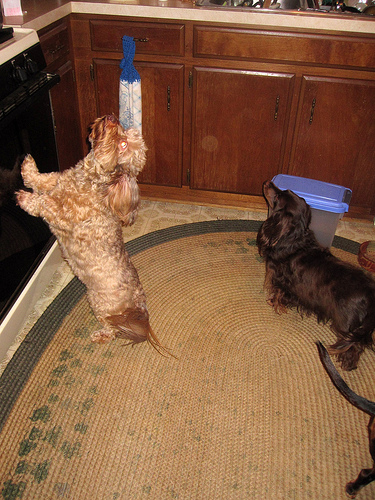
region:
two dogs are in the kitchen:
[15, 110, 369, 359]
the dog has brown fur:
[13, 110, 176, 364]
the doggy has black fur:
[255, 177, 373, 369]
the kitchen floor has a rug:
[6, 186, 374, 474]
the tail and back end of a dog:
[308, 335, 373, 491]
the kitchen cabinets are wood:
[41, 10, 373, 218]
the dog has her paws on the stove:
[0, 17, 131, 367]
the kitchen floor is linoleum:
[52, 196, 374, 263]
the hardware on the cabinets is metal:
[50, 2, 373, 185]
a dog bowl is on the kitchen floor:
[356, 235, 374, 276]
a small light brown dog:
[20, 105, 182, 373]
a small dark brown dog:
[249, 175, 372, 345]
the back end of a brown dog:
[306, 333, 374, 495]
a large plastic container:
[271, 170, 346, 255]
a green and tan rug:
[0, 219, 372, 496]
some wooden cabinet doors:
[85, 22, 373, 213]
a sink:
[194, 1, 374, 18]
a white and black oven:
[0, 39, 90, 367]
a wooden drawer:
[81, 19, 192, 55]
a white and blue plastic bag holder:
[115, 35, 147, 162]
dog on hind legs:
[13, 128, 158, 371]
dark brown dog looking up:
[242, 179, 363, 362]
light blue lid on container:
[271, 167, 358, 259]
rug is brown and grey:
[63, 217, 317, 498]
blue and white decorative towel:
[103, 37, 153, 157]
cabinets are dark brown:
[93, 24, 357, 190]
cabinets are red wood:
[82, 19, 349, 190]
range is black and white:
[0, 34, 65, 296]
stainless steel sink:
[205, 0, 343, 17]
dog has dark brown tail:
[107, 294, 191, 384]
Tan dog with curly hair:
[0, 17, 182, 371]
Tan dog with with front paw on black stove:
[5, 30, 182, 374]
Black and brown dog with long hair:
[230, 154, 373, 364]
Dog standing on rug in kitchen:
[233, 162, 373, 350]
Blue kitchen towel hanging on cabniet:
[101, 26, 168, 140]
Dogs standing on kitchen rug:
[21, 109, 372, 385]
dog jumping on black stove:
[17, 111, 202, 369]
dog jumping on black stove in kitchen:
[15, 98, 192, 361]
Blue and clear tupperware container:
[234, 128, 364, 269]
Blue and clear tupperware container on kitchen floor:
[244, 148, 357, 298]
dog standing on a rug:
[9, 110, 171, 362]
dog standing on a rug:
[245, 174, 373, 370]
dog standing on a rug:
[307, 337, 373, 497]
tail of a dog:
[315, 334, 365, 424]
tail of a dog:
[107, 296, 186, 367]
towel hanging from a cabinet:
[106, 35, 156, 171]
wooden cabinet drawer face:
[80, 17, 195, 57]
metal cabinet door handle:
[271, 91, 282, 126]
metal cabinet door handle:
[305, 91, 323, 126]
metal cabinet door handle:
[116, 34, 161, 44]